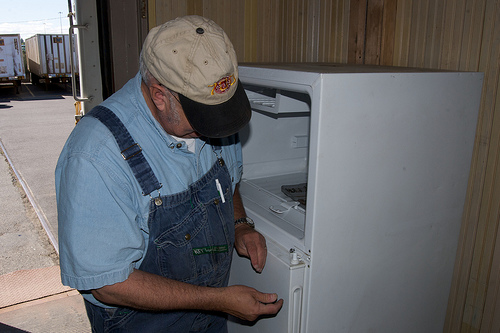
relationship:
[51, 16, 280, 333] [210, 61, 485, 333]
guy next to freezer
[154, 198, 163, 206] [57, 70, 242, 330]
button on clothes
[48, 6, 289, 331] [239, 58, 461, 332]
guy checking refrigerator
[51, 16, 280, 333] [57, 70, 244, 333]
guy wearing clothes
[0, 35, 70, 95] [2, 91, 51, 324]
trucks parked in yard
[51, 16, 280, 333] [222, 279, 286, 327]
guy has hands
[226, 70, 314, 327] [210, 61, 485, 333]
door on freezer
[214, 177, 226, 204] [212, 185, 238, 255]
pen in pocket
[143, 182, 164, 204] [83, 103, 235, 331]
buckle on overalls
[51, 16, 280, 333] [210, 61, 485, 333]
guy repairing freezer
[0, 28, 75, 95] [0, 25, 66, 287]
trucks parked in parking lot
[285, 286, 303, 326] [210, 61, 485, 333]
handle section on freezer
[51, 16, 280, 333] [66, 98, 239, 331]
guy wearing overalls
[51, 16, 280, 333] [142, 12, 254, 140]
guy wearing hat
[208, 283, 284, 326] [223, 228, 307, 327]
hand on refrigerator door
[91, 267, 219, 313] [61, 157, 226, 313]
skin on arm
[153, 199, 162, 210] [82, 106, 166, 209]
button on strap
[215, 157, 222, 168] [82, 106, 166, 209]
button on strap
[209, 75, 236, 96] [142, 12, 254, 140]
logo on hat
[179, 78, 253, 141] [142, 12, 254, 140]
bill on hat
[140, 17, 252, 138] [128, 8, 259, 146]
cap on head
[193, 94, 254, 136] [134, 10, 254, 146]
bill on hat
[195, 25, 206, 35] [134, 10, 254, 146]
tip on hat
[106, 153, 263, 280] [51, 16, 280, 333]
overalls on guy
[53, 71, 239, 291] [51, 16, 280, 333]
blue sleeve on guy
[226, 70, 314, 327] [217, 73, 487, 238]
door taken off freezer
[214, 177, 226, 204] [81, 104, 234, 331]
pen in front pocket of overall